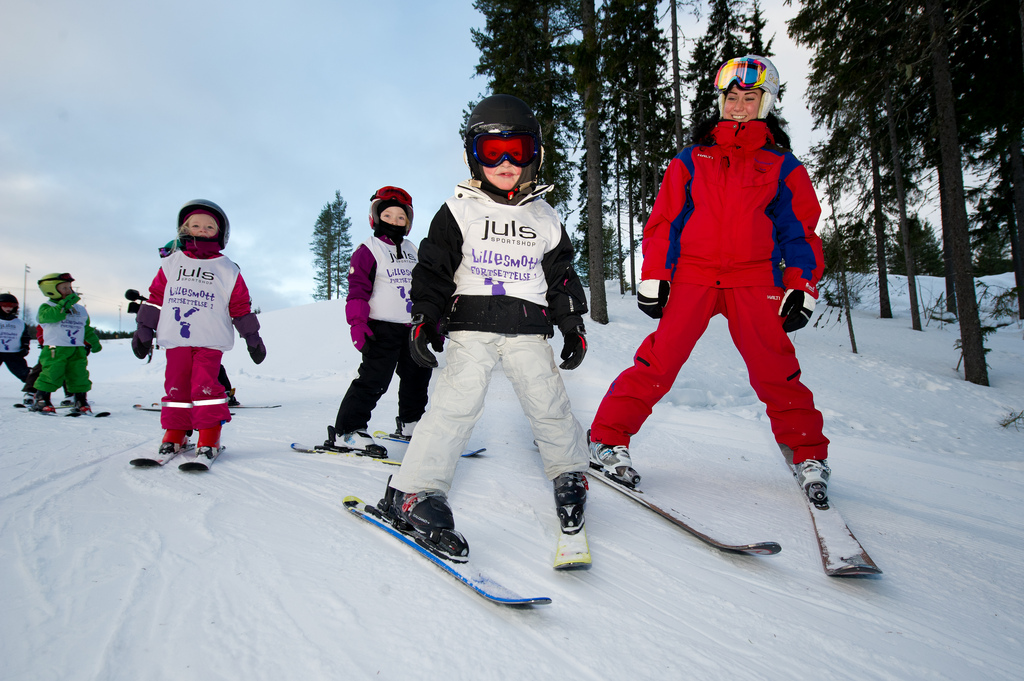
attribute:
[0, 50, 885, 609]
people — skiing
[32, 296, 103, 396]
suit — green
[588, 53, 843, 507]
instructor — smiling, teaching, children's ski instructor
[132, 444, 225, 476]
skis — black 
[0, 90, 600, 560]
children — skiing, cold, enjoying themselves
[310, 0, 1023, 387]
trees — green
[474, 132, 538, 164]
goggles — red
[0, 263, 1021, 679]
snow — white, groovy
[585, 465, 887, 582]
skis — brown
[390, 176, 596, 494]
suit — black, white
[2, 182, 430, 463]
children — behind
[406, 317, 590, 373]
gloves — black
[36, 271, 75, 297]
helmet — green, pea green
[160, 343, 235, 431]
pants — pink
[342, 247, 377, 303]
jacket — purple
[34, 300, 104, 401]
outfit — green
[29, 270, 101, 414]
child — looking to their left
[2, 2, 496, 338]
sky — cloudy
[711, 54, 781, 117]
helmet — white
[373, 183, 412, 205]
goggles — red, black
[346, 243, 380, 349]
arms — purple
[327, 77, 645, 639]
kid — in the front